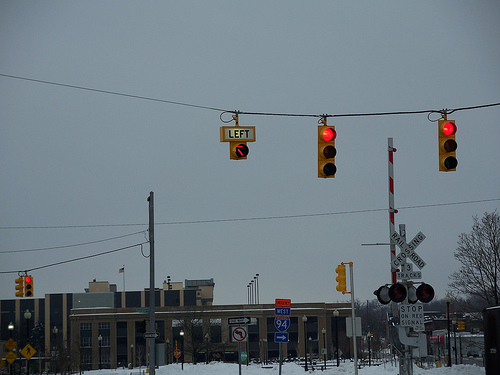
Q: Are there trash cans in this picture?
A: No, there are no trash cans.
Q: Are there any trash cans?
A: No, there are no trash cans.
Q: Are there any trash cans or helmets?
A: No, there are no trash cans or helmets.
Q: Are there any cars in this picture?
A: No, there are no cars.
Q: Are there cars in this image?
A: No, there are no cars.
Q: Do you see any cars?
A: No, there are no cars.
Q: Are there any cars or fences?
A: No, there are no cars or fences.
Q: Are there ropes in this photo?
A: No, there are no ropes.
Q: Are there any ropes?
A: No, there are no ropes.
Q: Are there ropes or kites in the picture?
A: No, there are no ropes or kites.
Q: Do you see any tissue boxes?
A: No, there are no tissue boxes.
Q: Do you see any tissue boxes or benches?
A: No, there are no tissue boxes or benches.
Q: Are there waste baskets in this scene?
A: No, there are no waste baskets.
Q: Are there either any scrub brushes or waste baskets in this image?
A: No, there are no waste baskets or scrub brushes.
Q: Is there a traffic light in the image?
A: Yes, there is a traffic light.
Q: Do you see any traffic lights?
A: Yes, there is a traffic light.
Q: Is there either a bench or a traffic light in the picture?
A: Yes, there is a traffic light.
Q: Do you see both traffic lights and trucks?
A: No, there is a traffic light but no trucks.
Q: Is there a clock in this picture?
A: No, there are no clocks.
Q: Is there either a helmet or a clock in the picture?
A: No, there are no clocks or helmets.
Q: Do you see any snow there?
A: Yes, there is snow.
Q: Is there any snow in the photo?
A: Yes, there is snow.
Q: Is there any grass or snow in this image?
A: Yes, there is snow.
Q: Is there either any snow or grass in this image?
A: Yes, there is snow.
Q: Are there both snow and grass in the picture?
A: No, there is snow but no grass.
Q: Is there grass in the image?
A: No, there is no grass.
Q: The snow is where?
A: The snow is on the ground.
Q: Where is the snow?
A: The snow is on the ground.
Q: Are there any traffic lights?
A: Yes, there is a traffic light.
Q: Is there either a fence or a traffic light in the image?
A: Yes, there is a traffic light.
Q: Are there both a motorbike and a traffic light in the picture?
A: No, there is a traffic light but no motorcycles.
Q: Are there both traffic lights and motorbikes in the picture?
A: No, there is a traffic light but no motorcycles.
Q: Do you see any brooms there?
A: No, there are no brooms.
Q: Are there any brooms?
A: No, there are no brooms.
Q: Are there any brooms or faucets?
A: No, there are no brooms or faucets.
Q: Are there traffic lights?
A: Yes, there is a traffic light.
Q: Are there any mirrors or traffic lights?
A: Yes, there is a traffic light.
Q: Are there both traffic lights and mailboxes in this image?
A: No, there is a traffic light but no mailboxes.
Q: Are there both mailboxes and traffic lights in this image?
A: No, there is a traffic light but no mailboxes.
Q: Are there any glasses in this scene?
A: No, there are no glasses.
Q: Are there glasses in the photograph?
A: No, there are no glasses.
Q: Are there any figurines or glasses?
A: No, there are no glasses or figurines.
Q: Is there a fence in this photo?
A: No, there are no fences.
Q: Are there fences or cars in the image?
A: No, there are no fences or cars.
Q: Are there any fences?
A: No, there are no fences.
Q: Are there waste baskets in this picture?
A: No, there are no waste baskets.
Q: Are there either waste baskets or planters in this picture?
A: No, there are no waste baskets or planters.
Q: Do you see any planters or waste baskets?
A: No, there are no waste baskets or planters.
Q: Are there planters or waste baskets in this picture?
A: No, there are no waste baskets or planters.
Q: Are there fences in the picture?
A: No, there are no fences.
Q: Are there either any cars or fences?
A: No, there are no fences or cars.